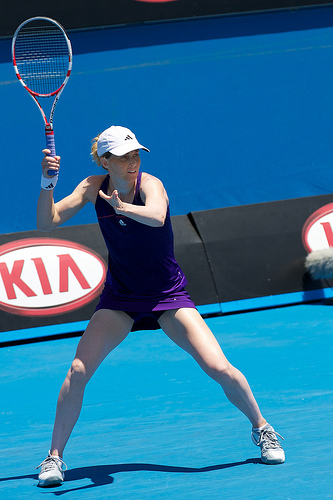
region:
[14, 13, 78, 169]
tennis raquet in hand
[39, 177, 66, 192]
white wristband on right arm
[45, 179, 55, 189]
adidas logo on wristband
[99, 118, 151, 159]
white hat on woman's head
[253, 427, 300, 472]
shoe on left foot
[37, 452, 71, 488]
shoe on the right foot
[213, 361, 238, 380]
the woman's left knee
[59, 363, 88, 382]
the woman's right knee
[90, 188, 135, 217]
the woman's left hand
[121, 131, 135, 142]
adidas logo on hat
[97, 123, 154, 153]
white hat on head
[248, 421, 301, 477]
shoe on woman's left foot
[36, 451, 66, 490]
shoe on woman's right foot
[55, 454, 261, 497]
the woman's shadow on the ground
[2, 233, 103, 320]
kia logo on wall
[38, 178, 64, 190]
white wristband on her arm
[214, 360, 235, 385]
the woman's left knee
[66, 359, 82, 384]
the woman's right knee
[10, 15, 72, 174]
A red, white, and blue tennis racket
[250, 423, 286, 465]
A white athletic shoe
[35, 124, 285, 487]
A female tennis player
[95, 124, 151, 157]
A white baseball hat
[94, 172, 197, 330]
A purple tennis uniform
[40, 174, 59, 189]
A white wrist band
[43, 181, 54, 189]
A black Adidas logo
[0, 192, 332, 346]
A tennis court barrier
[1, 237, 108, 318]
A red and white Kia logo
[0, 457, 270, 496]
A tennis player's shadow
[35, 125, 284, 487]
Woman playing tennis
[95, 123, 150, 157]
Hat on the woman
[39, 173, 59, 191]
Bracer on the woman's wrist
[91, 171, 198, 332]
Purple sport suit on the woman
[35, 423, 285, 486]
Shoes on the woman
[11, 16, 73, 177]
Racket in the woman's right hand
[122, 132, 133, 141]
Brand logo on the woman's hat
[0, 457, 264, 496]
Shadow of the woman on the tennis court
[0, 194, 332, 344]
Boards on the tennis court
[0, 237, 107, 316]
KIA logo on the board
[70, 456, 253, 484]
Shadow from woman player.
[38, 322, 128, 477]
Tennis player with toned legs.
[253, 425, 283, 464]
Foot slightly raised off of the ground.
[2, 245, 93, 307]
KIA logo in the background.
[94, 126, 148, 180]
White hat on woman's head.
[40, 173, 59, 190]
White wrist band on wrist.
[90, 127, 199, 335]
Woman in purple tennis gear.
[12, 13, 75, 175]
Woman holding tennis racket.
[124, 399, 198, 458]
Light blue tennis court.